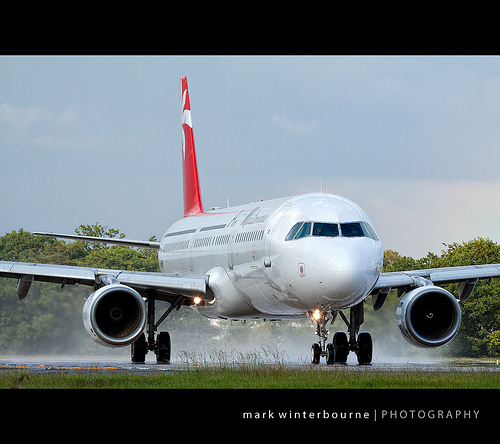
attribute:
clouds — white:
[65, 110, 430, 221]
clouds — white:
[5, 123, 192, 224]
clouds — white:
[1, 87, 126, 164]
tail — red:
[172, 71, 207, 212]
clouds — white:
[233, 84, 399, 176]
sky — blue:
[5, 53, 435, 164]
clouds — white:
[377, 179, 482, 219]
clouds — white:
[224, 114, 309, 154]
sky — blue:
[222, 82, 279, 143]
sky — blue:
[4, 59, 497, 236]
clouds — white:
[358, 172, 495, 237]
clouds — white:
[3, 102, 116, 157]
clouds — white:
[6, 61, 494, 258]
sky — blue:
[2, 59, 498, 255]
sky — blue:
[4, 56, 499, 274]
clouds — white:
[259, 111, 499, 256]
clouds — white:
[262, 103, 330, 150]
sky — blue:
[4, 57, 496, 190]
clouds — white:
[273, 84, 484, 166]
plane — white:
[0, 76, 499, 365]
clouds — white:
[299, 178, 496, 257]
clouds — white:
[363, 138, 459, 227]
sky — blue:
[201, 89, 277, 147]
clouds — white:
[20, 68, 94, 142]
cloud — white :
[8, 91, 123, 160]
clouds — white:
[304, 93, 399, 162]